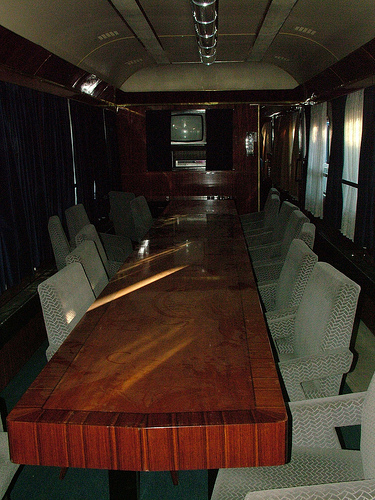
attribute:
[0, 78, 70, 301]
curtain — dark blue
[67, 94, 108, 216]
curtain — dark blue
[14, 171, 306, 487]
table — long, brown, wooden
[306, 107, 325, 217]
curtains — sheer, white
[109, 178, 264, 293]
table — wooden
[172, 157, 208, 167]
device — electronic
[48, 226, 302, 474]
wooden table — brown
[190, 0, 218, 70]
lighting — overhead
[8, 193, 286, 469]
table — wood, extremely long, wooden, large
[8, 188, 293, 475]
wooden table — brown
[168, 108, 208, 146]
tv — old-fashioned, high-mounted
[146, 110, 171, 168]
curtains — black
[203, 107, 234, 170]
curtains — black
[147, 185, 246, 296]
wood table — long, dusty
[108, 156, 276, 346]
table — long, conference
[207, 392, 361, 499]
chair — white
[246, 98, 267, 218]
pole — gold